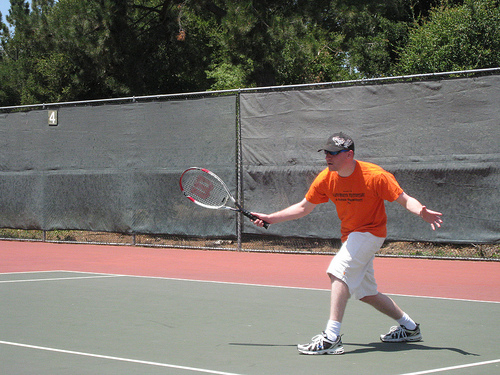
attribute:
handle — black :
[235, 207, 271, 230]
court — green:
[1, 235, 495, 372]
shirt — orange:
[304, 157, 405, 244]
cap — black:
[315, 126, 363, 157]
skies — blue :
[2, 4, 34, 32]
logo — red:
[192, 174, 213, 201]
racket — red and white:
[179, 164, 271, 231]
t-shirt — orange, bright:
[308, 166, 401, 234]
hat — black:
[296, 120, 361, 162]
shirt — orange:
[308, 170, 406, 227]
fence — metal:
[5, 62, 497, 267]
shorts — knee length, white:
[323, 229, 386, 301]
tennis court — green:
[4, 270, 497, 374]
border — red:
[0, 231, 499, 305]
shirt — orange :
[271, 117, 427, 249]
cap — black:
[317, 130, 353, 152]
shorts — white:
[316, 220, 409, 275]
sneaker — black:
[276, 309, 441, 364]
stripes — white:
[297, 327, 349, 356]